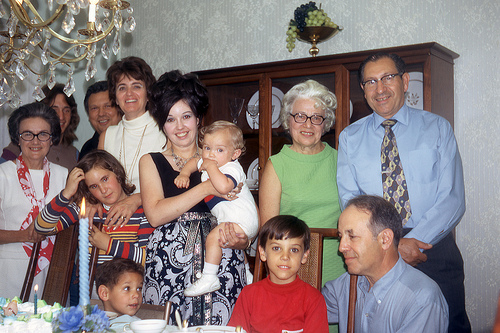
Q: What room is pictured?
A: It is a dining room.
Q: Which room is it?
A: It is a dining room.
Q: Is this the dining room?
A: Yes, it is the dining room.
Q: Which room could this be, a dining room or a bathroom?
A: It is a dining room.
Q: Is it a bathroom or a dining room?
A: It is a dining room.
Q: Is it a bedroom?
A: No, it is a dining room.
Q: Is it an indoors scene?
A: Yes, it is indoors.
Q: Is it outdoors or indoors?
A: It is indoors.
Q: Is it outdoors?
A: No, it is indoors.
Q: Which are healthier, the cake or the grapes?
A: The grapes are healthier than the cake.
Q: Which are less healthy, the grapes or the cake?
A: The cake are less healthy than the grapes.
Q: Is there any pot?
A: No, there are no pots.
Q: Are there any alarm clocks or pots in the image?
A: No, there are no pots or alarm clocks.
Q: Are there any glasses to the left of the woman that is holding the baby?
A: No, the glasses are to the right of the woman.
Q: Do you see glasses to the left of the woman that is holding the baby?
A: No, the glasses are to the right of the woman.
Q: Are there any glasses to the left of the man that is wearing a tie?
A: Yes, there are glasses to the left of the man.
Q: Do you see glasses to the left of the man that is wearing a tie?
A: Yes, there are glasses to the left of the man.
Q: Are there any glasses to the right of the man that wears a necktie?
A: No, the glasses are to the left of the man.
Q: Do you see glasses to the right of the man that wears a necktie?
A: No, the glasses are to the left of the man.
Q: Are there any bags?
A: No, there are no bags.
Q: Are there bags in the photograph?
A: No, there are no bags.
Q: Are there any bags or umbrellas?
A: No, there are no bags or umbrellas.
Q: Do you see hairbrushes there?
A: No, there are no hairbrushes.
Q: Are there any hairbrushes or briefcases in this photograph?
A: No, there are no hairbrushes or briefcases.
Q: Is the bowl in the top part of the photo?
A: Yes, the bowl is in the top of the image.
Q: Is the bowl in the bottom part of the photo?
A: No, the bowl is in the top of the image.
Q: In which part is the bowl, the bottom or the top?
A: The bowl is in the top of the image.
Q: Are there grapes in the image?
A: Yes, there are grapes.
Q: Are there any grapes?
A: Yes, there are grapes.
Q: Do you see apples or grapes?
A: Yes, there are grapes.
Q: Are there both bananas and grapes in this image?
A: No, there are grapes but no bananas.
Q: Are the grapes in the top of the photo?
A: Yes, the grapes are in the top of the image.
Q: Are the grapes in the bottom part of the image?
A: No, the grapes are in the top of the image.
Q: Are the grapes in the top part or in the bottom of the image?
A: The grapes are in the top of the image.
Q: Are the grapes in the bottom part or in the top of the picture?
A: The grapes are in the top of the image.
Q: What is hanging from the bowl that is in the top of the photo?
A: The grapes are hanging from the bowl.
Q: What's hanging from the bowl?
A: The grapes are hanging from the bowl.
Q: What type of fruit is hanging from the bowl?
A: The fruits are grapes.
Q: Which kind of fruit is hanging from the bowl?
A: The fruits are grapes.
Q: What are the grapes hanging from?
A: The grapes are hanging from the bowl.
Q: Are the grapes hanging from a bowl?
A: Yes, the grapes are hanging from a bowl.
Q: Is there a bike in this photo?
A: No, there are no bikes.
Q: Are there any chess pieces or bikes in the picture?
A: No, there are no bikes or chess pieces.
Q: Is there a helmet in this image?
A: No, there are no helmets.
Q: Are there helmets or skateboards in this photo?
A: No, there are no helmets or skateboards.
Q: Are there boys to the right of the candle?
A: Yes, there is a boy to the right of the candle.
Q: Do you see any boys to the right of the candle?
A: Yes, there is a boy to the right of the candle.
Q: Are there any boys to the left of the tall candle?
A: No, the boy is to the right of the candle.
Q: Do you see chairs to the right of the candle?
A: No, there is a boy to the right of the candle.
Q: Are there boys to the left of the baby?
A: Yes, there is a boy to the left of the baby.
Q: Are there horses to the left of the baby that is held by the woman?
A: No, there is a boy to the left of the baby.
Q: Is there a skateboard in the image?
A: No, there are no skateboards.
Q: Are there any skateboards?
A: No, there are no skateboards.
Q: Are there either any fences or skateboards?
A: No, there are no skateboards or fences.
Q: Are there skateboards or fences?
A: No, there are no skateboards or fences.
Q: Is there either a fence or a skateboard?
A: No, there are no skateboards or fences.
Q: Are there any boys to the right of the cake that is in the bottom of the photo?
A: Yes, there is a boy to the right of the cake.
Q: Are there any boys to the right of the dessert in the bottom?
A: Yes, there is a boy to the right of the cake.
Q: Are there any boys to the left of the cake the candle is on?
A: No, the boy is to the right of the cake.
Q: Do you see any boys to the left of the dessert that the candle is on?
A: No, the boy is to the right of the cake.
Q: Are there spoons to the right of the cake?
A: No, there is a boy to the right of the cake.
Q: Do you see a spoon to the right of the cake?
A: No, there is a boy to the right of the cake.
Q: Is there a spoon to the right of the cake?
A: No, there is a boy to the right of the cake.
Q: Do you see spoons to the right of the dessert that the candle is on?
A: No, there is a boy to the right of the cake.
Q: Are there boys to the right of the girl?
A: Yes, there is a boy to the right of the girl.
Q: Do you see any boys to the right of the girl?
A: Yes, there is a boy to the right of the girl.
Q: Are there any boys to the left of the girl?
A: No, the boy is to the right of the girl.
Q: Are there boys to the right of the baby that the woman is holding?
A: Yes, there is a boy to the right of the baby.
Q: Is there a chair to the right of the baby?
A: No, there is a boy to the right of the baby.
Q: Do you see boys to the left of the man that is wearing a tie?
A: Yes, there is a boy to the left of the man.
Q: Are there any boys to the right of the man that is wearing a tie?
A: No, the boy is to the left of the man.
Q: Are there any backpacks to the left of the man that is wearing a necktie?
A: No, there is a boy to the left of the man.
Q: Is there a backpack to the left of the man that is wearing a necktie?
A: No, there is a boy to the left of the man.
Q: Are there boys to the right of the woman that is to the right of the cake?
A: Yes, there is a boy to the right of the woman.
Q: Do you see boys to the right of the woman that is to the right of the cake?
A: Yes, there is a boy to the right of the woman.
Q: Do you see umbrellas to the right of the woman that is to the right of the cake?
A: No, there is a boy to the right of the woman.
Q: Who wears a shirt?
A: The boy wears a shirt.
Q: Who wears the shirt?
A: The boy wears a shirt.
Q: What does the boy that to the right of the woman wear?
A: The boy wears a shirt.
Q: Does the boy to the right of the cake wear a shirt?
A: Yes, the boy wears a shirt.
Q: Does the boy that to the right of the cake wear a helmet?
A: No, the boy wears a shirt.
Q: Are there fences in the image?
A: No, there are no fences.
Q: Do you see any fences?
A: No, there are no fences.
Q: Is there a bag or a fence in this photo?
A: No, there are no fences or bags.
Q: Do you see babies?
A: Yes, there is a baby.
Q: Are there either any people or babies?
A: Yes, there is a baby.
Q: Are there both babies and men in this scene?
A: Yes, there are both a baby and a man.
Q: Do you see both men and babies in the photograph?
A: Yes, there are both a baby and a man.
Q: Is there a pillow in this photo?
A: No, there are no pillows.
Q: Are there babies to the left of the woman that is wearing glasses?
A: Yes, there is a baby to the left of the woman.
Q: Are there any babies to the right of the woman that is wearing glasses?
A: No, the baby is to the left of the woman.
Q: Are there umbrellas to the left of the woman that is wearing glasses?
A: No, there is a baby to the left of the woman.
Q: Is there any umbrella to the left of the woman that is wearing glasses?
A: No, there is a baby to the left of the woman.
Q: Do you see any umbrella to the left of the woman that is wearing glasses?
A: No, there is a baby to the left of the woman.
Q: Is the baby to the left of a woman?
A: Yes, the baby is to the left of a woman.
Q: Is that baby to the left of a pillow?
A: No, the baby is to the left of a woman.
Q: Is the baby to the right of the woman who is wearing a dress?
A: No, the baby is to the left of the woman.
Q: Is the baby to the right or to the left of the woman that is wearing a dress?
A: The baby is to the left of the woman.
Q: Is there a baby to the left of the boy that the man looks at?
A: Yes, there is a baby to the left of the boy.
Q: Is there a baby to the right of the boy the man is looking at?
A: No, the baby is to the left of the boy.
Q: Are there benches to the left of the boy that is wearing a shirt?
A: No, there is a baby to the left of the boy.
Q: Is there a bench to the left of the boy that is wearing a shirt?
A: No, there is a baby to the left of the boy.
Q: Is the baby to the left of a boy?
A: Yes, the baby is to the left of a boy.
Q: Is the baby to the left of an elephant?
A: No, the baby is to the left of a boy.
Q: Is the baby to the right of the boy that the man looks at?
A: No, the baby is to the left of the boy.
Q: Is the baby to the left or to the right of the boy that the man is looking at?
A: The baby is to the left of the boy.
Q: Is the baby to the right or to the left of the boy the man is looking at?
A: The baby is to the left of the boy.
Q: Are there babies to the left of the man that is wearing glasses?
A: Yes, there is a baby to the left of the man.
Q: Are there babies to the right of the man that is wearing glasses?
A: No, the baby is to the left of the man.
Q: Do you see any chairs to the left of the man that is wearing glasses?
A: No, there is a baby to the left of the man.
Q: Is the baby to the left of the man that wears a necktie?
A: Yes, the baby is to the left of the man.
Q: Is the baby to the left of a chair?
A: No, the baby is to the left of the man.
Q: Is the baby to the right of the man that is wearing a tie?
A: No, the baby is to the left of the man.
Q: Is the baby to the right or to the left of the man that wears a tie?
A: The baby is to the left of the man.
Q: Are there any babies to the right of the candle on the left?
A: Yes, there is a baby to the right of the candle.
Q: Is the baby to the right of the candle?
A: Yes, the baby is to the right of the candle.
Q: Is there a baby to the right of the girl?
A: Yes, there is a baby to the right of the girl.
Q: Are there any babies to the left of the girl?
A: No, the baby is to the right of the girl.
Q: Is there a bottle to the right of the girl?
A: No, there is a baby to the right of the girl.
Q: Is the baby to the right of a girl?
A: Yes, the baby is to the right of a girl.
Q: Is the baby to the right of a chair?
A: No, the baby is to the right of a girl.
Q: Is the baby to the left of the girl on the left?
A: No, the baby is to the right of the girl.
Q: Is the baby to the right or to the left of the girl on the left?
A: The baby is to the right of the girl.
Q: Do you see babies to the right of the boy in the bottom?
A: Yes, there is a baby to the right of the boy.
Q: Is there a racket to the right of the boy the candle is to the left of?
A: No, there is a baby to the right of the boy.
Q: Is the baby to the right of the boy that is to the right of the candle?
A: Yes, the baby is to the right of the boy.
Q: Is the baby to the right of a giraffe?
A: No, the baby is to the right of the boy.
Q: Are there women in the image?
A: Yes, there is a woman.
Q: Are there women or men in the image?
A: Yes, there is a woman.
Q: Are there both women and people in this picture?
A: Yes, there are both a woman and a person.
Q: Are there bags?
A: No, there are no bags.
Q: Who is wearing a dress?
A: The woman is wearing a dress.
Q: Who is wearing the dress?
A: The woman is wearing a dress.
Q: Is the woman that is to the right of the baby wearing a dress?
A: Yes, the woman is wearing a dress.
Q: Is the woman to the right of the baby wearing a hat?
A: No, the woman is wearing a dress.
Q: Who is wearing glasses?
A: The woman is wearing glasses.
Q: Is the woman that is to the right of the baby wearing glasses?
A: Yes, the woman is wearing glasses.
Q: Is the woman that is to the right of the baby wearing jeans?
A: No, the woman is wearing glasses.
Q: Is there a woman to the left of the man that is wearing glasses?
A: Yes, there is a woman to the left of the man.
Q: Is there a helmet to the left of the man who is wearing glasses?
A: No, there is a woman to the left of the man.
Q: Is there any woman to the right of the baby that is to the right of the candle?
A: Yes, there is a woman to the right of the baby.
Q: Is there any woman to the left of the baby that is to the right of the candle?
A: No, the woman is to the right of the baby.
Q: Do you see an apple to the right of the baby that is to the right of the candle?
A: No, there is a woman to the right of the baby.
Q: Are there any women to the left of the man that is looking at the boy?
A: Yes, there is a woman to the left of the man.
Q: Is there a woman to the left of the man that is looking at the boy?
A: Yes, there is a woman to the left of the man.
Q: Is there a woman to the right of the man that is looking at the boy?
A: No, the woman is to the left of the man.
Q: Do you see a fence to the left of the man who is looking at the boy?
A: No, there is a woman to the left of the man.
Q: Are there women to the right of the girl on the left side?
A: Yes, there is a woman to the right of the girl.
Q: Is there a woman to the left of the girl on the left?
A: No, the woman is to the right of the girl.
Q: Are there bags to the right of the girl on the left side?
A: No, there is a woman to the right of the girl.